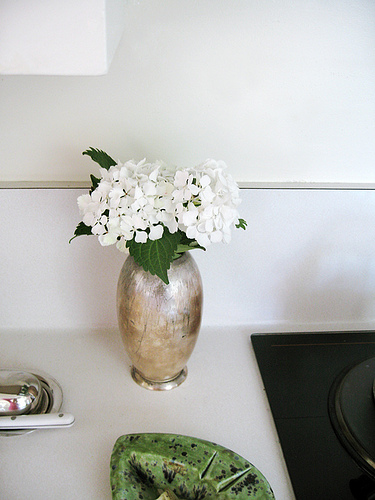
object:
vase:
[116, 252, 204, 391]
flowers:
[77, 156, 241, 255]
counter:
[0, 328, 375, 498]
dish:
[0, 370, 74, 434]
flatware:
[0, 414, 79, 428]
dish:
[109, 432, 275, 500]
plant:
[72, 146, 251, 283]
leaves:
[82, 145, 115, 168]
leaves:
[127, 226, 203, 282]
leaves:
[69, 222, 100, 243]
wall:
[0, 4, 372, 192]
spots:
[171, 452, 178, 463]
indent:
[199, 451, 218, 479]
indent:
[219, 463, 254, 491]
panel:
[250, 330, 375, 498]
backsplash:
[3, 180, 375, 326]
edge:
[0, 180, 374, 194]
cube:
[0, 3, 108, 77]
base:
[128, 366, 193, 390]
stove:
[252, 330, 373, 496]